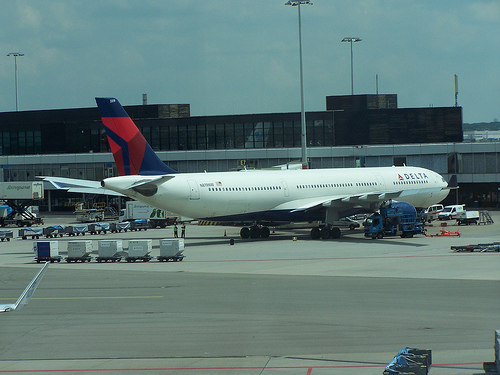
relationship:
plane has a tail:
[36, 95, 462, 239] [35, 96, 179, 215]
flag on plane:
[216, 179, 225, 187] [36, 95, 462, 239]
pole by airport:
[283, 0, 316, 166] [0, 93, 498, 215]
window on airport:
[323, 116, 337, 147] [0, 93, 498, 215]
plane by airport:
[36, 95, 462, 239] [0, 93, 498, 215]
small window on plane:
[296, 182, 299, 190] [36, 95, 462, 239]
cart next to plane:
[156, 238, 188, 262] [36, 95, 462, 239]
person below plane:
[173, 222, 179, 240] [36, 95, 462, 239]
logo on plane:
[395, 172, 430, 181] [36, 95, 462, 239]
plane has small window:
[36, 95, 462, 239] [296, 182, 299, 190]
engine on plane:
[323, 196, 395, 218] [36, 95, 462, 239]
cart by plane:
[156, 238, 188, 262] [36, 95, 462, 239]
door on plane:
[186, 173, 202, 202] [36, 95, 462, 239]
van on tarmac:
[438, 202, 467, 221] [2, 210, 497, 371]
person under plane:
[173, 222, 179, 240] [36, 95, 462, 239]